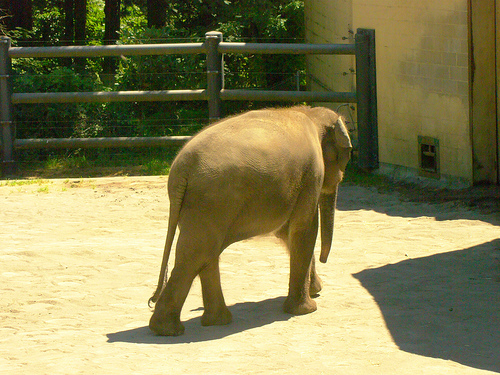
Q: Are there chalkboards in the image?
A: No, there are no chalkboards.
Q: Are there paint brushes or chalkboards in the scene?
A: No, there are no chalkboards or paint brushes.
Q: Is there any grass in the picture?
A: Yes, there is grass.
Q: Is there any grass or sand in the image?
A: Yes, there is grass.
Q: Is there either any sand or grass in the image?
A: Yes, there is grass.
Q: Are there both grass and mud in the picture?
A: No, there is grass but no mud.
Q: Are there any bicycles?
A: No, there are no bicycles.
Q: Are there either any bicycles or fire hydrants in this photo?
A: No, there are no bicycles or fire hydrants.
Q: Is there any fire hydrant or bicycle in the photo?
A: No, there are no bicycles or fire hydrants.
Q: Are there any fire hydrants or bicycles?
A: No, there are no bicycles or fire hydrants.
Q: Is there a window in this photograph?
A: Yes, there is a window.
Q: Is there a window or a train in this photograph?
A: Yes, there is a window.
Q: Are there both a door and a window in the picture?
A: No, there is a window but no doors.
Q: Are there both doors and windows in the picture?
A: No, there is a window but no doors.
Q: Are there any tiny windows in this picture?
A: Yes, there is a tiny window.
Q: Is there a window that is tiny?
A: Yes, there is a window that is tiny.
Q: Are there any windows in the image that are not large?
A: Yes, there is a tiny window.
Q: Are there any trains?
A: No, there are no trains.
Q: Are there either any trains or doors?
A: No, there are no trains or doors.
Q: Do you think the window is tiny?
A: Yes, the window is tiny.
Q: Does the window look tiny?
A: Yes, the window is tiny.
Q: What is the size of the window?
A: The window is tiny.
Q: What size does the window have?
A: The window has tiny size.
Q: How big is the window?
A: The window is tiny.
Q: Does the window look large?
A: No, the window is tiny.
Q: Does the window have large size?
A: No, the window is tiny.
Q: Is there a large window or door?
A: No, there is a window but it is tiny.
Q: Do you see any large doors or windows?
A: No, there is a window but it is tiny.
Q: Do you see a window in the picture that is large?
A: No, there is a window but it is tiny.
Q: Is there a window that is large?
A: No, there is a window but it is tiny.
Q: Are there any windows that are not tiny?
A: No, there is a window but it is tiny.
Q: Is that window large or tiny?
A: The window is tiny.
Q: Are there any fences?
A: Yes, there is a fence.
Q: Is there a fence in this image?
A: Yes, there is a fence.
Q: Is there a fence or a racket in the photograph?
A: Yes, there is a fence.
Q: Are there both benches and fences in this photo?
A: No, there is a fence but no benches.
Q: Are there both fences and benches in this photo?
A: No, there is a fence but no benches.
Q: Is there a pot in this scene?
A: No, there are no pots.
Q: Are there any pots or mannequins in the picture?
A: No, there are no pots or mannequins.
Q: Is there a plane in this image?
A: No, there are no airplanes.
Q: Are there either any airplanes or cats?
A: No, there are no airplanes or cats.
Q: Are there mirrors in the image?
A: No, there are no mirrors.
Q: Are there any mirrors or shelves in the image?
A: No, there are no mirrors or shelves.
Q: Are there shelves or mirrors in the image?
A: No, there are no mirrors or shelves.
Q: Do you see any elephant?
A: Yes, there is an elephant.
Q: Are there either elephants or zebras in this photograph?
A: Yes, there is an elephant.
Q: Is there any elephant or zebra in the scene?
A: Yes, there is an elephant.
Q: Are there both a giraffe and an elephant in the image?
A: No, there is an elephant but no giraffes.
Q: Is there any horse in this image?
A: No, there are no horses.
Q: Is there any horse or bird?
A: No, there are no horses or birds.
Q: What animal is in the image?
A: The animal is an elephant.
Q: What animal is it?
A: The animal is an elephant.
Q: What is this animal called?
A: This is an elephant.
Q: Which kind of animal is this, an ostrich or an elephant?
A: This is an elephant.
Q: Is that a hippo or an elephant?
A: That is an elephant.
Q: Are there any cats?
A: No, there are no cats.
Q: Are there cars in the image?
A: No, there are no cars.